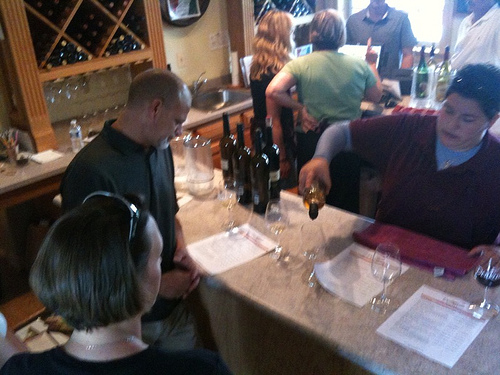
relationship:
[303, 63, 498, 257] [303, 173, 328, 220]
man holding bottle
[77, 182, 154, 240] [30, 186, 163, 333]
glasses on woman's head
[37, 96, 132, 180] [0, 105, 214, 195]
bottle of water on counter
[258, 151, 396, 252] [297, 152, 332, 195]
bottle in hand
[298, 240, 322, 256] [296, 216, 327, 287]
wine in glass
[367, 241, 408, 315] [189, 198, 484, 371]
glass on a bar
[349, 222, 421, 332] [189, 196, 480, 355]
glass on counter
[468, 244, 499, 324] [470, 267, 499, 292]
glass with wine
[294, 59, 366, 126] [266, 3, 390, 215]
green shirt on woman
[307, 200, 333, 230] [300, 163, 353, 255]
tip on bottle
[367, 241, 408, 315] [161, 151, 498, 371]
glass on counter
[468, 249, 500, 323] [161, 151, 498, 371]
glass on counter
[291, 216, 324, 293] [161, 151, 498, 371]
glass on counter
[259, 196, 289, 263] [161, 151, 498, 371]
glass on counter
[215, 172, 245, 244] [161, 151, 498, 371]
glass on counter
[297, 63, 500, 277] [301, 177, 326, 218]
man pouring wine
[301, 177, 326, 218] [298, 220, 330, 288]
wine into glass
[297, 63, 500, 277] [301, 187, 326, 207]
man pouring wine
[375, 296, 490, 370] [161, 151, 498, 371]
paper on counter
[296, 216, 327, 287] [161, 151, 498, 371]
glass on counter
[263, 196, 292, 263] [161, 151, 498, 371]
glass on counter